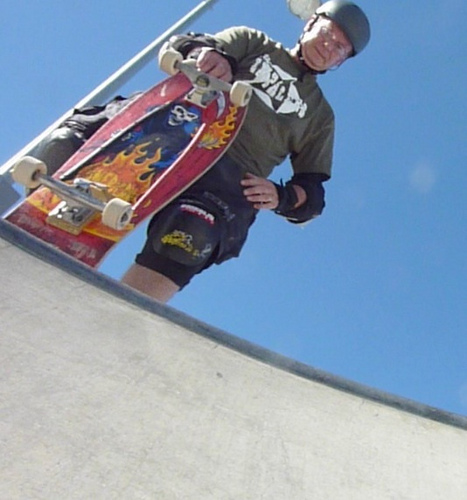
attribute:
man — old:
[111, 3, 372, 309]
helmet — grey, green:
[313, 0, 375, 65]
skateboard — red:
[6, 39, 257, 272]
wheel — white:
[229, 80, 256, 112]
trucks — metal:
[48, 178, 112, 231]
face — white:
[164, 102, 201, 134]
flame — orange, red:
[74, 139, 165, 205]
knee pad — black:
[148, 198, 226, 277]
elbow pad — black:
[290, 175, 327, 229]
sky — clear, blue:
[5, 6, 465, 316]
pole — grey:
[8, 7, 210, 174]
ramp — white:
[0, 229, 463, 498]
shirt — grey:
[207, 19, 338, 200]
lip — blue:
[211, 329, 464, 441]